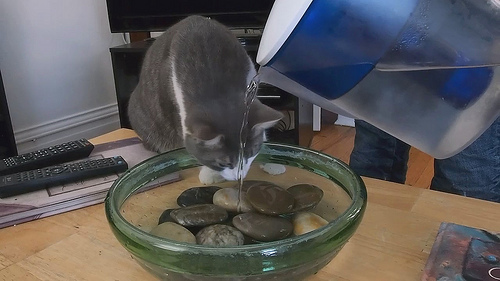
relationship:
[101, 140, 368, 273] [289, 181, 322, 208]
bowl with rock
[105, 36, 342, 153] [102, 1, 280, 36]
stand with television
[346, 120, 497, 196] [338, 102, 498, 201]
legs with jeans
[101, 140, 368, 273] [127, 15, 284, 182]
bowl with cat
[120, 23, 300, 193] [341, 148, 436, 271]
cat on table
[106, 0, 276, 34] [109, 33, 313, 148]
television on television stand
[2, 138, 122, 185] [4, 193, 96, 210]
remotes atop book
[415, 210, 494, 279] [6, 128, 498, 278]
book on table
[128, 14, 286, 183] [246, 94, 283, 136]
cat has ear